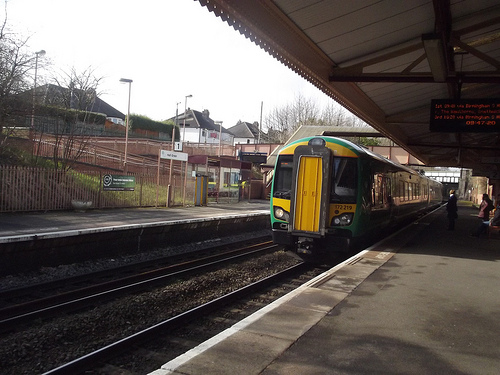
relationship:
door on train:
[292, 156, 323, 231] [273, 137, 445, 239]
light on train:
[273, 209, 285, 219] [267, 122, 499, 267]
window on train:
[275, 167, 294, 198] [267, 122, 499, 267]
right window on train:
[326, 153, 361, 208] [267, 122, 499, 267]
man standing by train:
[443, 186, 461, 237] [267, 122, 499, 267]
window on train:
[397, 177, 407, 202] [267, 122, 499, 267]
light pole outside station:
[108, 70, 136, 175] [1, 0, 496, 365]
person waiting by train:
[445, 186, 459, 234] [267, 122, 499, 267]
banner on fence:
[101, 171, 137, 191] [8, 161, 257, 216]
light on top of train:
[305, 132, 329, 151] [267, 122, 499, 267]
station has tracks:
[1, 0, 496, 365] [42, 258, 327, 371]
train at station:
[267, 122, 499, 267] [167, 116, 283, 263]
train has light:
[267, 122, 499, 267] [267, 196, 289, 224]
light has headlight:
[267, 196, 289, 224] [333, 218, 342, 226]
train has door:
[267, 122, 499, 267] [288, 154, 326, 237]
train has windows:
[267, 122, 499, 267] [396, 181, 427, 203]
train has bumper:
[267, 122, 499, 267] [269, 226, 349, 268]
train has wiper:
[267, 122, 499, 267] [276, 187, 290, 196]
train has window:
[273, 134, 375, 244] [433, 183, 440, 198]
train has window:
[273, 134, 375, 244] [427, 185, 434, 200]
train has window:
[273, 134, 375, 244] [415, 180, 420, 196]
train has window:
[273, 134, 375, 244] [406, 179, 413, 201]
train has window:
[273, 134, 375, 244] [398, 178, 405, 201]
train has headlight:
[267, 122, 499, 267] [271, 207, 286, 219]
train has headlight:
[267, 122, 499, 267] [333, 212, 353, 226]